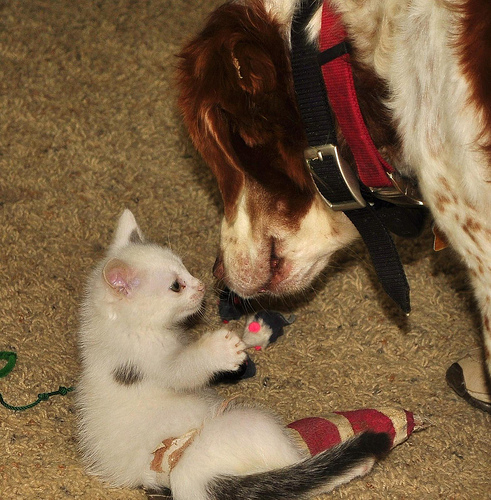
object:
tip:
[445, 349, 465, 403]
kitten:
[65, 207, 391, 499]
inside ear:
[102, 258, 133, 297]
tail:
[204, 430, 395, 498]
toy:
[286, 406, 432, 458]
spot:
[109, 364, 144, 384]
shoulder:
[87, 336, 150, 390]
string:
[0, 342, 77, 418]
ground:
[0, 0, 228, 414]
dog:
[172, 1, 490, 302]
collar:
[288, 0, 412, 313]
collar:
[291, 2, 367, 219]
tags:
[431, 220, 448, 255]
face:
[169, 0, 345, 306]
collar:
[318, 0, 395, 193]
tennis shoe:
[444, 345, 490, 414]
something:
[224, 36, 269, 98]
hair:
[181, 0, 225, 122]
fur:
[92, 329, 169, 467]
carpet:
[0, 0, 173, 207]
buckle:
[301, 142, 366, 211]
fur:
[401, 0, 490, 226]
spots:
[433, 174, 490, 247]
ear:
[223, 28, 270, 99]